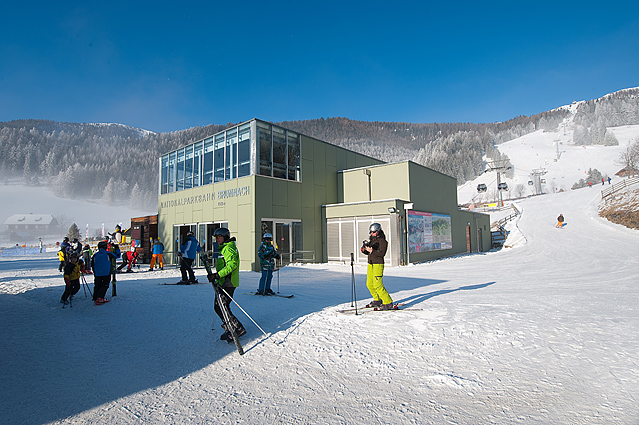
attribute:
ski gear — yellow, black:
[360, 235, 404, 314]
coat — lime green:
[215, 242, 242, 302]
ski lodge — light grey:
[132, 112, 506, 297]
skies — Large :
[54, 8, 192, 93]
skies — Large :
[33, 18, 204, 93]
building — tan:
[150, 117, 471, 278]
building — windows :
[143, 118, 495, 273]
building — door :
[177, 220, 189, 249]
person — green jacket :
[206, 231, 260, 362]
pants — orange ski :
[144, 252, 163, 268]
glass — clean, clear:
[228, 139, 253, 172]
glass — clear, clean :
[237, 134, 253, 179]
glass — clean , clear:
[237, 132, 247, 179]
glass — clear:
[211, 135, 236, 182]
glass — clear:
[260, 127, 275, 174]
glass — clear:
[274, 132, 289, 174]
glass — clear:
[287, 133, 299, 177]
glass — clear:
[165, 142, 205, 190]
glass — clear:
[231, 132, 261, 170]